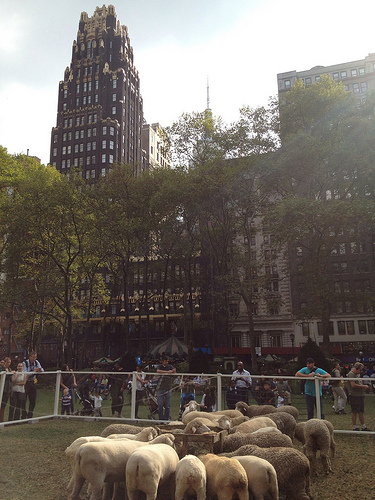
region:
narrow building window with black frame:
[300, 320, 310, 335]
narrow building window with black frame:
[316, 321, 324, 337]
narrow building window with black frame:
[326, 320, 335, 334]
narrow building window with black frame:
[336, 319, 345, 335]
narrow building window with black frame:
[346, 319, 355, 334]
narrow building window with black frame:
[357, 319, 365, 334]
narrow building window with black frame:
[368, 320, 374, 332]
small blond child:
[61, 387, 72, 413]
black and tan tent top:
[146, 332, 187, 355]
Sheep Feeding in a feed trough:
[53, 388, 339, 493]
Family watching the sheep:
[0, 349, 49, 418]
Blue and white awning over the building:
[149, 331, 194, 362]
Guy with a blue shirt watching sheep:
[289, 348, 330, 413]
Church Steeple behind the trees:
[177, 69, 238, 162]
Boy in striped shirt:
[55, 384, 74, 417]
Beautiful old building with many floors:
[32, 3, 165, 177]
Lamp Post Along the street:
[283, 328, 299, 362]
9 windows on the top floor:
[275, 66, 373, 91]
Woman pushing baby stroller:
[134, 359, 168, 420]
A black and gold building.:
[42, 5, 142, 175]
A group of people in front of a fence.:
[3, 339, 373, 428]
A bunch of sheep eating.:
[57, 400, 337, 498]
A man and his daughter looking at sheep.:
[225, 361, 250, 407]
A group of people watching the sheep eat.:
[2, 348, 327, 499]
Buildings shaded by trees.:
[12, 68, 374, 343]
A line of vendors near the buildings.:
[81, 326, 374, 399]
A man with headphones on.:
[346, 360, 367, 431]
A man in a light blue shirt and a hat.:
[295, 358, 330, 419]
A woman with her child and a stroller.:
[60, 362, 92, 414]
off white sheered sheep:
[124, 442, 177, 498]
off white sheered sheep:
[77, 436, 173, 497]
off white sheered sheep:
[174, 451, 207, 499]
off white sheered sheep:
[197, 452, 245, 497]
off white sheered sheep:
[230, 455, 276, 496]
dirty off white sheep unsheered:
[215, 446, 309, 495]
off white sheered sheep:
[215, 432, 289, 449]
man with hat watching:
[295, 355, 328, 425]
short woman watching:
[10, 361, 26, 421]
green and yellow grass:
[0, 386, 371, 496]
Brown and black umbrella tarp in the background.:
[149, 334, 194, 357]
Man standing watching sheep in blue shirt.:
[292, 358, 341, 415]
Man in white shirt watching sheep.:
[228, 356, 259, 415]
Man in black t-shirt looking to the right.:
[157, 347, 176, 409]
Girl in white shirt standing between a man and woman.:
[11, 360, 29, 420]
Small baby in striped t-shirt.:
[57, 388, 75, 416]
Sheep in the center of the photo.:
[51, 372, 349, 496]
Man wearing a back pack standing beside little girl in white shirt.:
[23, 346, 52, 418]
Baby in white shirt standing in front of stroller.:
[84, 386, 110, 422]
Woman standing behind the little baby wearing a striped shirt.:
[61, 358, 89, 412]